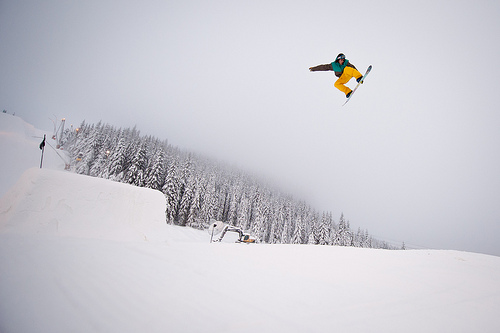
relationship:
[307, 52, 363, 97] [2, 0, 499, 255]
man in air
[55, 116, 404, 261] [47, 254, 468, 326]
pine trees covered by snow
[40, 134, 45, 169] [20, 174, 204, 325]
post sticking out of snow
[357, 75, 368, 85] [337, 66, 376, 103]
hand holding snowboard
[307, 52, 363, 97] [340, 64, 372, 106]
man on snowboard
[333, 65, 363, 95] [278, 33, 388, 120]
pants on person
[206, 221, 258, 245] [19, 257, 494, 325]
object in snow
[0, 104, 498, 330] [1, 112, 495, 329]
expanse in snow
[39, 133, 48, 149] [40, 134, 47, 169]
black flag in post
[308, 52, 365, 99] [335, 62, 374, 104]
man on snowboard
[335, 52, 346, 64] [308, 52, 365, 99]
head on man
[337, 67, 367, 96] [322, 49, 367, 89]
pants on man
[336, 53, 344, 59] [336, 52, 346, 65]
goggles on head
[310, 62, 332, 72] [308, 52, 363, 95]
arm on person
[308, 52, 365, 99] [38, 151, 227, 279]
man off jump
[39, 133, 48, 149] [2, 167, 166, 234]
black flag on jump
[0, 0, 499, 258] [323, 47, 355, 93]
sky on person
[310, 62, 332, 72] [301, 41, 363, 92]
arm on snowboarder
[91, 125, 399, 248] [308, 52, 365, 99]
trees behind man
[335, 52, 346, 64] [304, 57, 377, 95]
head of person